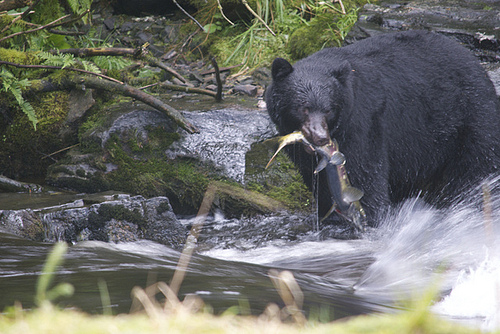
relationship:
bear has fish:
[263, 30, 497, 237] [260, 128, 367, 233]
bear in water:
[263, 30, 497, 237] [0, 224, 496, 289]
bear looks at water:
[263, 30, 497, 237] [5, 185, 499, 334]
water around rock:
[5, 185, 499, 334] [5, 187, 224, 272]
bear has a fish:
[263, 30, 497, 237] [260, 128, 367, 233]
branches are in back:
[3, 5, 226, 118] [8, 1, 190, 70]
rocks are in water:
[89, 85, 311, 244] [5, 185, 499, 334]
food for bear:
[260, 128, 367, 233] [263, 30, 497, 237]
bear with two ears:
[263, 30, 497, 237] [269, 57, 352, 86]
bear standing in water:
[263, 30, 497, 237] [0, 224, 496, 289]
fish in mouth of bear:
[260, 128, 367, 233] [263, 30, 497, 237]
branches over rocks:
[3, 5, 226, 118] [89, 85, 311, 244]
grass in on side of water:
[3, 5, 359, 90] [0, 224, 496, 289]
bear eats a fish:
[263, 30, 497, 237] [260, 128, 367, 233]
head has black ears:
[262, 57, 354, 154] [269, 57, 352, 86]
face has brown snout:
[264, 51, 357, 145] [294, 107, 333, 151]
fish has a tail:
[260, 128, 367, 233] [258, 128, 303, 171]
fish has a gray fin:
[260, 128, 367, 233] [260, 122, 282, 173]